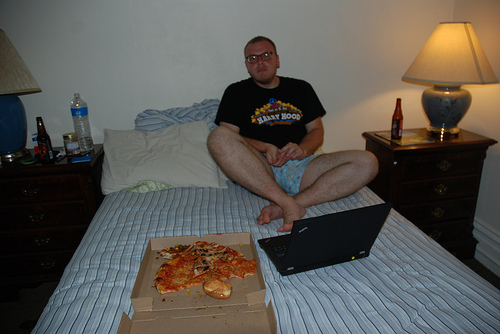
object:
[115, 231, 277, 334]
box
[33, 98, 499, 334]
bed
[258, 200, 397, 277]
laptop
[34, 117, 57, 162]
bottle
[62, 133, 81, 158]
stand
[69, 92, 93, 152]
water bottle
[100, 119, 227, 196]
pillow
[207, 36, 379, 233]
man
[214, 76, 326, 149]
shirt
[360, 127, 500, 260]
nightstand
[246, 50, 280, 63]
glasses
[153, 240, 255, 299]
pizza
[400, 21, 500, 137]
lamp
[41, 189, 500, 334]
sheet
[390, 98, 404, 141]
bottle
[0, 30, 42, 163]
lamp